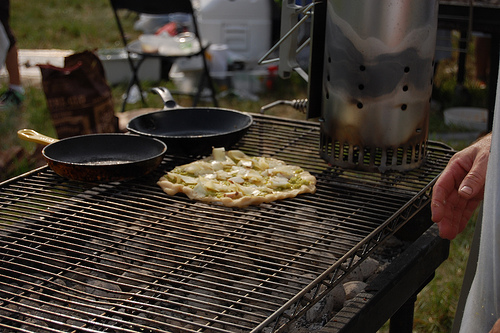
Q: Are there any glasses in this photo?
A: No, there are no glasses.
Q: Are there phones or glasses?
A: No, there are no glasses or phones.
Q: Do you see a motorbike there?
A: No, there are no motorcycles.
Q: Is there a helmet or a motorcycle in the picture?
A: No, there are no motorcycles or helmets.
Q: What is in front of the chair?
A: The grill is in front of the chair.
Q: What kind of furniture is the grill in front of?
A: The grill is in front of the chair.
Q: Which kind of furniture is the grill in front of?
A: The grill is in front of the chair.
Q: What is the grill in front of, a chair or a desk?
A: The grill is in front of a chair.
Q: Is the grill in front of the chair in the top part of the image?
A: Yes, the grill is in front of the chair.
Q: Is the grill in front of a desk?
A: No, the grill is in front of the chair.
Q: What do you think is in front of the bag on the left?
A: The grill is in front of the bag.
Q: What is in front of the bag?
A: The grill is in front of the bag.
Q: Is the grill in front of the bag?
A: Yes, the grill is in front of the bag.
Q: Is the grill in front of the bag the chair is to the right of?
A: Yes, the grill is in front of the bag.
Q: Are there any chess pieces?
A: No, there are no chess pieces.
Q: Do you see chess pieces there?
A: No, there are no chess pieces.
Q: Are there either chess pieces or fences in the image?
A: No, there are no chess pieces or fences.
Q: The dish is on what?
A: The dish is on the grill.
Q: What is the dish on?
A: The dish is on the grill.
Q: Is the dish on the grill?
A: Yes, the dish is on the grill.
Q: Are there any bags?
A: Yes, there is a bag.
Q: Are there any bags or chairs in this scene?
A: Yes, there is a bag.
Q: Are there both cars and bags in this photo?
A: No, there is a bag but no cars.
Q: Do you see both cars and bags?
A: No, there is a bag but no cars.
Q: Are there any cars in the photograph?
A: No, there are no cars.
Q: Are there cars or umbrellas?
A: No, there are no cars or umbrellas.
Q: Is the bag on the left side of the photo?
A: Yes, the bag is on the left of the image.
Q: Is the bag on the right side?
A: No, the bag is on the left of the image.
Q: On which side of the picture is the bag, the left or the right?
A: The bag is on the left of the image.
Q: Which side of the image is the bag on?
A: The bag is on the left of the image.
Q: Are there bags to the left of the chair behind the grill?
A: Yes, there is a bag to the left of the chair.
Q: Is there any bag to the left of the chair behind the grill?
A: Yes, there is a bag to the left of the chair.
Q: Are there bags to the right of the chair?
A: No, the bag is to the left of the chair.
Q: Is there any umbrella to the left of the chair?
A: No, there is a bag to the left of the chair.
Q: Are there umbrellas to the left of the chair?
A: No, there is a bag to the left of the chair.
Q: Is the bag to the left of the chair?
A: Yes, the bag is to the left of the chair.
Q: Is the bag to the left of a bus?
A: No, the bag is to the left of the chair.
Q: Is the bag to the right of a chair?
A: No, the bag is to the left of a chair.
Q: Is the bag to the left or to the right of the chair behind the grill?
A: The bag is to the left of the chair.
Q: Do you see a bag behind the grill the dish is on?
A: Yes, there is a bag behind the grill.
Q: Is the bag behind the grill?
A: Yes, the bag is behind the grill.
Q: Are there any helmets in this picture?
A: No, there are no helmets.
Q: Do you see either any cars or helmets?
A: No, there are no helmets or cars.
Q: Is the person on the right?
A: Yes, the person is on the right of the image.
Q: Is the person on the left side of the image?
A: No, the person is on the right of the image.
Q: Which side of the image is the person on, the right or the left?
A: The person is on the right of the image.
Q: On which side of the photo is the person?
A: The person is on the right of the image.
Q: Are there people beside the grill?
A: Yes, there is a person beside the grill.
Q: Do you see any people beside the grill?
A: Yes, there is a person beside the grill.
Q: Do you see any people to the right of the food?
A: Yes, there is a person to the right of the food.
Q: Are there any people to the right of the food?
A: Yes, there is a person to the right of the food.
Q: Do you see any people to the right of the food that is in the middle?
A: Yes, there is a person to the right of the food.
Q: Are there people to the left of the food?
A: No, the person is to the right of the food.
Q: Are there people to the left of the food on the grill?
A: No, the person is to the right of the food.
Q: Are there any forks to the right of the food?
A: No, there is a person to the right of the food.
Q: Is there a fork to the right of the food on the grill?
A: No, there is a person to the right of the food.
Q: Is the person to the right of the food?
A: Yes, the person is to the right of the food.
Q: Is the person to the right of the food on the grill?
A: Yes, the person is to the right of the food.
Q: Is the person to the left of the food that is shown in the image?
A: No, the person is to the right of the food.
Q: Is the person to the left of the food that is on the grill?
A: No, the person is to the right of the food.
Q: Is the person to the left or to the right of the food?
A: The person is to the right of the food.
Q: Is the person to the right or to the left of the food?
A: The person is to the right of the food.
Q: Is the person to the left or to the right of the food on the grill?
A: The person is to the right of the food.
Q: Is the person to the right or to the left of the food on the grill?
A: The person is to the right of the food.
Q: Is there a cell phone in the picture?
A: No, there are no cell phones.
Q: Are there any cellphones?
A: No, there are no cellphones.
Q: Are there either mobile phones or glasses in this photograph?
A: No, there are no mobile phones or glasses.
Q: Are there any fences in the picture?
A: No, there are no fences.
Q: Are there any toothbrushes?
A: No, there are no toothbrushes.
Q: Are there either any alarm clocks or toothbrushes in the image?
A: No, there are no toothbrushes or alarm clocks.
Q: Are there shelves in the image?
A: No, there are no shelves.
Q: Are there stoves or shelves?
A: No, there are no shelves or stoves.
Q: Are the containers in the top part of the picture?
A: Yes, the containers are in the top of the image.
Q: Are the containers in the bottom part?
A: No, the containers are in the top of the image.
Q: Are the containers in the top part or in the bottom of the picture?
A: The containers are in the top of the image.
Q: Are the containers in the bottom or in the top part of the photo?
A: The containers are in the top of the image.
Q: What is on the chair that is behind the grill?
A: The containers are on the chair.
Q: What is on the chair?
A: The containers are on the chair.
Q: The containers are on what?
A: The containers are on the chair.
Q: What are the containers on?
A: The containers are on the chair.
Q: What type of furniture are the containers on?
A: The containers are on the chair.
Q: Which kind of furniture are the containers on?
A: The containers are on the chair.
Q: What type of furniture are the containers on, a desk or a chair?
A: The containers are on a chair.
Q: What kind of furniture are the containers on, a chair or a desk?
A: The containers are on a chair.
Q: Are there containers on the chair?
A: Yes, there are containers on the chair.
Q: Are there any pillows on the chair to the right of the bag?
A: No, there are containers on the chair.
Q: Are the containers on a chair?
A: Yes, the containers are on a chair.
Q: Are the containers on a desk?
A: No, the containers are on a chair.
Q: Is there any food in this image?
A: Yes, there is food.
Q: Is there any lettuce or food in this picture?
A: Yes, there is food.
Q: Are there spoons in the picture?
A: No, there are no spoons.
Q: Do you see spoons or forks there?
A: No, there are no spoons or forks.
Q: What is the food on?
A: The food is on the grill.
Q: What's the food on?
A: The food is on the grill.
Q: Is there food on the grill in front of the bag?
A: Yes, there is food on the grill.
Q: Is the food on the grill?
A: Yes, the food is on the grill.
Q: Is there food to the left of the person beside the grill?
A: Yes, there is food to the left of the person.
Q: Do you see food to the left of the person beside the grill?
A: Yes, there is food to the left of the person.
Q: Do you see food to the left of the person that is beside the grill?
A: Yes, there is food to the left of the person.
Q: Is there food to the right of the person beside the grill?
A: No, the food is to the left of the person.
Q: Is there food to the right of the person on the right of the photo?
A: No, the food is to the left of the person.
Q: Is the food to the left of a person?
A: Yes, the food is to the left of a person.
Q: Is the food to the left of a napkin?
A: No, the food is to the left of a person.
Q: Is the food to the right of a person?
A: No, the food is to the left of a person.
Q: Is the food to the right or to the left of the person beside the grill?
A: The food is to the left of the person.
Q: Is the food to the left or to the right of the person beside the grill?
A: The food is to the left of the person.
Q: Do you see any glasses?
A: No, there are no glasses.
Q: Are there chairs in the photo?
A: Yes, there is a chair.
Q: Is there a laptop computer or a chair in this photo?
A: Yes, there is a chair.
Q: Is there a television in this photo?
A: No, there are no televisions.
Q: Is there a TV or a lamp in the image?
A: No, there are no televisions or lamps.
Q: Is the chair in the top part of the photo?
A: Yes, the chair is in the top of the image.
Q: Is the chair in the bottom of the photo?
A: No, the chair is in the top of the image.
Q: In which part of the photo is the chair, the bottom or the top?
A: The chair is in the top of the image.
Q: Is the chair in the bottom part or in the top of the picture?
A: The chair is in the top of the image.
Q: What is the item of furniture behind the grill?
A: The piece of furniture is a chair.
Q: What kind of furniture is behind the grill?
A: The piece of furniture is a chair.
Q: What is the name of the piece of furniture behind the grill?
A: The piece of furniture is a chair.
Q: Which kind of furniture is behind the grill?
A: The piece of furniture is a chair.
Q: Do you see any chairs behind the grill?
A: Yes, there is a chair behind the grill.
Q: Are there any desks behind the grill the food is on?
A: No, there is a chair behind the grill.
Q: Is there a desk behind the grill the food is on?
A: No, there is a chair behind the grill.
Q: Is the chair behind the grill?
A: Yes, the chair is behind the grill.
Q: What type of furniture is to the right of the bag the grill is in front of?
A: The piece of furniture is a chair.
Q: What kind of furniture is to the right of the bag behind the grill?
A: The piece of furniture is a chair.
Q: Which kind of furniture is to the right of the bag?
A: The piece of furniture is a chair.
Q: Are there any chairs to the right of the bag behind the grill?
A: Yes, there is a chair to the right of the bag.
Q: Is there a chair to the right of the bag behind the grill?
A: Yes, there is a chair to the right of the bag.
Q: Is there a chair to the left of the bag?
A: No, the chair is to the right of the bag.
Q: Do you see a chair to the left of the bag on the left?
A: No, the chair is to the right of the bag.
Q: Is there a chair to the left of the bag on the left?
A: No, the chair is to the right of the bag.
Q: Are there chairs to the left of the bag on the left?
A: No, the chair is to the right of the bag.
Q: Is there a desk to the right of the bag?
A: No, there is a chair to the right of the bag.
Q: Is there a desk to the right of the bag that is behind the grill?
A: No, there is a chair to the right of the bag.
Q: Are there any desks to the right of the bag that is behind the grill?
A: No, there is a chair to the right of the bag.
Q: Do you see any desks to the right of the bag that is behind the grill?
A: No, there is a chair to the right of the bag.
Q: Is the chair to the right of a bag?
A: Yes, the chair is to the right of a bag.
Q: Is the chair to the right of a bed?
A: No, the chair is to the right of a bag.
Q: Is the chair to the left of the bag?
A: No, the chair is to the right of the bag.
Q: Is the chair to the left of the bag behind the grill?
A: No, the chair is to the right of the bag.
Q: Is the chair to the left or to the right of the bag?
A: The chair is to the right of the bag.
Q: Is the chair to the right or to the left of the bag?
A: The chair is to the right of the bag.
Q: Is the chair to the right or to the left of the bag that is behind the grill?
A: The chair is to the right of the bag.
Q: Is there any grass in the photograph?
A: Yes, there is grass.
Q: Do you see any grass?
A: Yes, there is grass.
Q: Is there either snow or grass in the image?
A: Yes, there is grass.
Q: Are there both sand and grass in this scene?
A: No, there is grass but no sand.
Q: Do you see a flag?
A: No, there are no flags.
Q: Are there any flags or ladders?
A: No, there are no flags or ladders.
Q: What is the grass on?
A: The grass is on the grill.